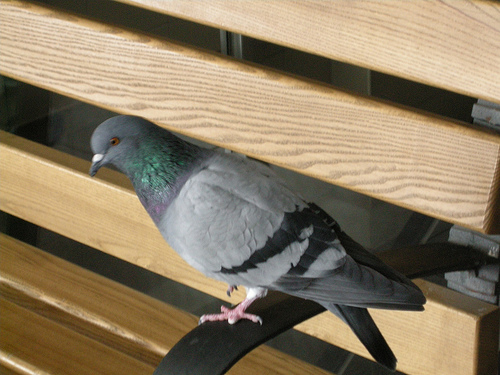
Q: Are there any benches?
A: Yes, there is a bench.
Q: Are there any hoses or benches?
A: Yes, there is a bench.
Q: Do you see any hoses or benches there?
A: Yes, there is a bench.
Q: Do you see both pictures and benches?
A: No, there is a bench but no pictures.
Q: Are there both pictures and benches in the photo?
A: No, there is a bench but no pictures.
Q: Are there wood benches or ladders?
A: Yes, there is a wood bench.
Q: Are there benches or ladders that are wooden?
A: Yes, the bench is wooden.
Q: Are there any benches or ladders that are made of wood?
A: Yes, the bench is made of wood.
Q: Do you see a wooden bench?
A: Yes, there is a wood bench.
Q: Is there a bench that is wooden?
A: Yes, there is a bench that is wooden.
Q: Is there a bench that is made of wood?
A: Yes, there is a bench that is made of wood.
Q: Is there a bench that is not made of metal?
A: Yes, there is a bench that is made of wood.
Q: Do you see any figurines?
A: No, there are no figurines.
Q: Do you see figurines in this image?
A: No, there are no figurines.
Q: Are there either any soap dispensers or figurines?
A: No, there are no figurines or soap dispensers.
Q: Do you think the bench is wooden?
A: Yes, the bench is wooden.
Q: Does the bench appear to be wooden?
A: Yes, the bench is wooden.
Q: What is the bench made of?
A: The bench is made of wood.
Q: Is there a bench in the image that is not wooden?
A: No, there is a bench but it is wooden.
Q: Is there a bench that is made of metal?
A: No, there is a bench but it is made of wood.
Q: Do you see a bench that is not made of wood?
A: No, there is a bench but it is made of wood.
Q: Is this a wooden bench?
A: Yes, this is a wooden bench.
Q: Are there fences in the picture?
A: No, there are no fences.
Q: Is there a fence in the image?
A: No, there are no fences.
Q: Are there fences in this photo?
A: No, there are no fences.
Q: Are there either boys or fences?
A: No, there are no fences or boys.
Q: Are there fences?
A: No, there are no fences.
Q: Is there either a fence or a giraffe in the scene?
A: No, there are no fences or giraffes.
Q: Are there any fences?
A: No, there are no fences.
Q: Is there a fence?
A: No, there are no fences.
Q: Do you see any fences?
A: No, there are no fences.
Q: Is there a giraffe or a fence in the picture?
A: No, there are no fences or giraffes.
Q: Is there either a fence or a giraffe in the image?
A: No, there are no fences or giraffes.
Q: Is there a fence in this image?
A: No, there are no fences.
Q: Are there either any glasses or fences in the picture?
A: No, there are no fences or glasses.